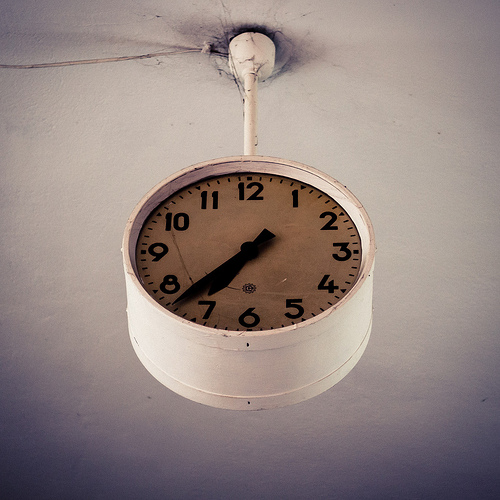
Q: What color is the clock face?
A: Brown.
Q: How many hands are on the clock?
A: Two.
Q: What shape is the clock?
A: Circle.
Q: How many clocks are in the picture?
A: One.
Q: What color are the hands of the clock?
A: Black.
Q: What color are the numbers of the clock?
A: Black.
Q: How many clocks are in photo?
A: 1.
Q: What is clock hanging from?
A: Ceiling.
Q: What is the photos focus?
A: Hanging clock.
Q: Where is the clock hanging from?
A: Ceiling.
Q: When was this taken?
A: Daytime.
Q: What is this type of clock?
A: Analog.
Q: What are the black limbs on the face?
A: Hands.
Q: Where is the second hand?
A: Missing.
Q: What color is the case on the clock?
A: White.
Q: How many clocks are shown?
A: 1.